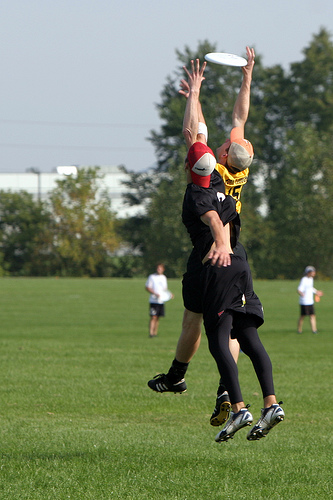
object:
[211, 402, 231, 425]
cleats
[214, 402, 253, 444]
boot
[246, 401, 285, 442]
boot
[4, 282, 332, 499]
grass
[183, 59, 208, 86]
hands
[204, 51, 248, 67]
frisbee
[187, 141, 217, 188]
cap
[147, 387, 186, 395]
cleats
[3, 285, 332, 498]
ground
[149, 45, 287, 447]
two men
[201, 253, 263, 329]
shorts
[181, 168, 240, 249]
sweater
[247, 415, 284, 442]
cleats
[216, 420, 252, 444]
cleats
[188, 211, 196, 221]
part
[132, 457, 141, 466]
part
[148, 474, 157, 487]
part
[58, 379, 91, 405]
part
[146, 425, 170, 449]
part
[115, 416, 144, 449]
part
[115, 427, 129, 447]
part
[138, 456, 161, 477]
part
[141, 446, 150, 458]
part